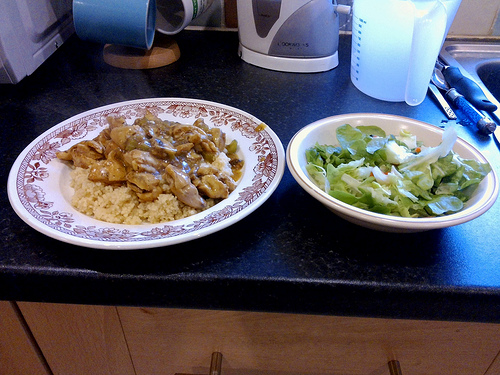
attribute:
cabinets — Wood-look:
[35, 304, 427, 374]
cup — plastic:
[342, 0, 467, 112]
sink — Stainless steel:
[440, 44, 496, 154]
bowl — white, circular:
[285, 108, 498, 234]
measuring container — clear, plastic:
[350, 0, 460, 114]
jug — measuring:
[344, 2, 466, 113]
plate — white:
[92, 222, 212, 258]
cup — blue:
[70, 0, 166, 50]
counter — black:
[0, 39, 500, 322]